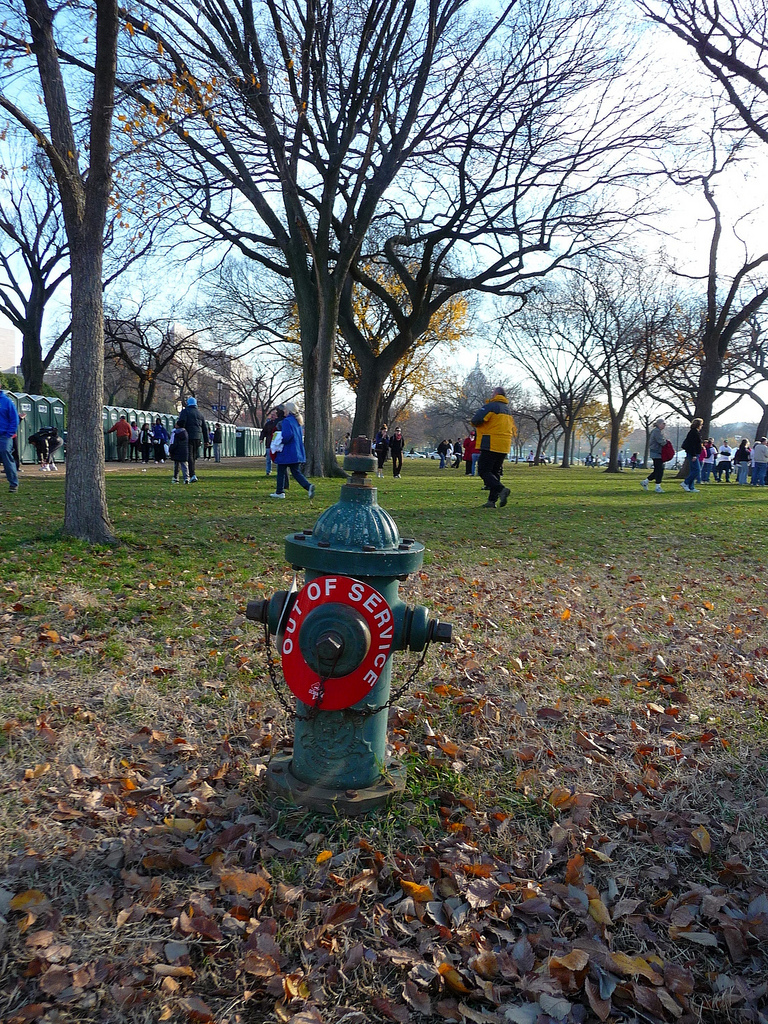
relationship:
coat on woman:
[264, 403, 305, 460] [270, 403, 339, 511]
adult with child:
[182, 418, 236, 476] [150, 424, 207, 511]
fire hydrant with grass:
[244, 464, 452, 803] [125, 479, 595, 544]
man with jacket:
[458, 395, 548, 515] [454, 386, 550, 464]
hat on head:
[182, 395, 205, 411] [182, 393, 198, 411]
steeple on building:
[469, 347, 487, 367] [439, 372, 507, 461]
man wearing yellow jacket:
[467, 381, 521, 514] [462, 389, 516, 457]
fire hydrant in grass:
[254, 448, 420, 804] [32, 477, 280, 591]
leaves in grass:
[13, 857, 761, 1021] [22, 762, 531, 858]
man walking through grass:
[467, 381, 521, 514] [427, 483, 600, 573]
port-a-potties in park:
[2, 389, 264, 468] [223, 280, 761, 705]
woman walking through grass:
[262, 402, 322, 502] [208, 456, 344, 541]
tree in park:
[34, 194, 144, 548] [143, 449, 762, 598]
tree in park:
[208, 18, 411, 477] [76, 427, 765, 869]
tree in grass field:
[520, 336, 599, 470] [491, 458, 703, 544]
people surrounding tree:
[565, 439, 627, 480] [582, 385, 611, 452]